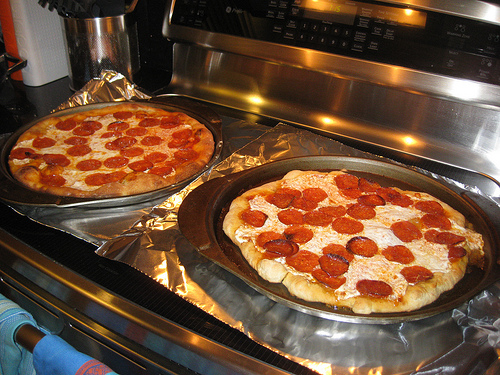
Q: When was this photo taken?
A: 7:15.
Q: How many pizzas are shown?
A: Two.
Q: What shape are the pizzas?
A: Circular.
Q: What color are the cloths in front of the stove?
A: Blue.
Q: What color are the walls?
A: White.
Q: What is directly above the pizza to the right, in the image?
A: Trash can.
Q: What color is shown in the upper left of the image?
A: Orange.